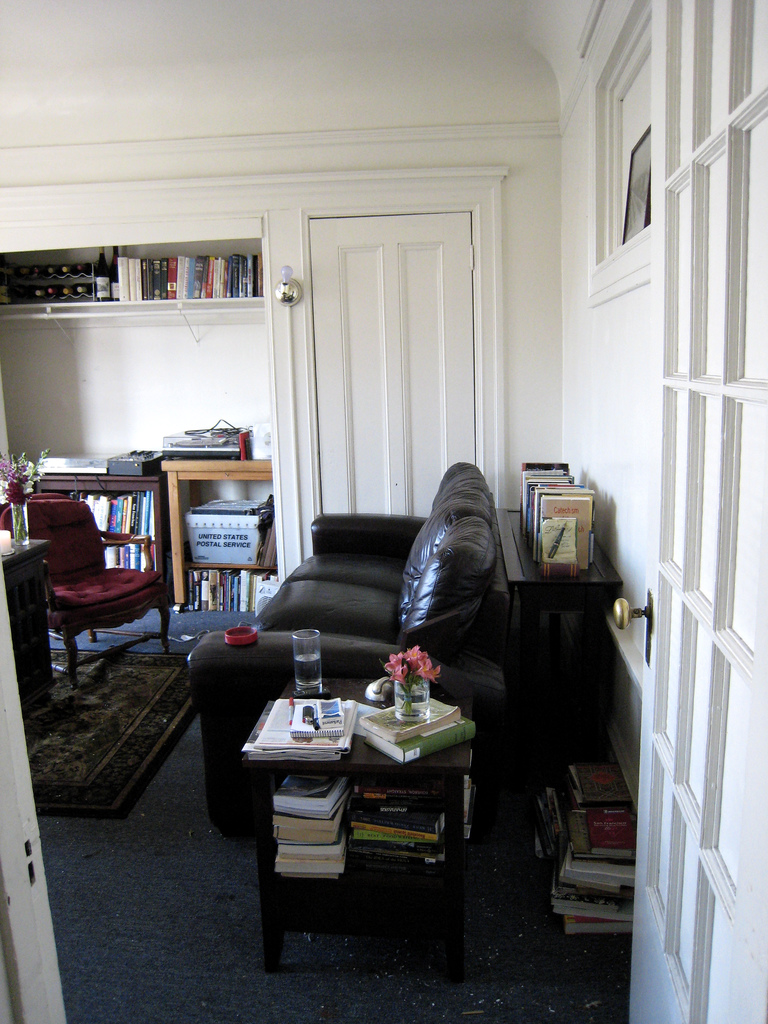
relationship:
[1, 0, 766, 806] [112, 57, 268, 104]
wall of building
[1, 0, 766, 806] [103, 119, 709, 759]
wall on building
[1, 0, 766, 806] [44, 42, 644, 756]
wall on building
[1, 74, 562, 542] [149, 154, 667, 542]
wall on building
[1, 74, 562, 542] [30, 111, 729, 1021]
wall on building